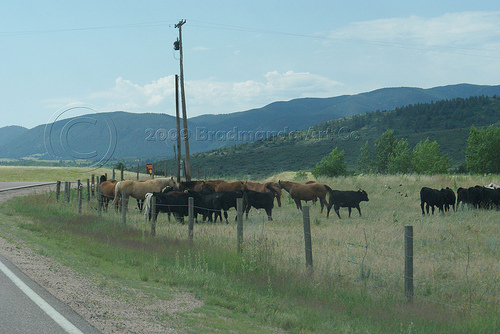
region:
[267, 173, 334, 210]
Horse grazing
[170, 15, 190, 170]
A power line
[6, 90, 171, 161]
mountains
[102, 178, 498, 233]
Livestock grazing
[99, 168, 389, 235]
Cows and horses grazing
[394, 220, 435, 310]
A pole for that is part of a fence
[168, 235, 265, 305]
grass and weeds on the roadside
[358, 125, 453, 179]
Green trees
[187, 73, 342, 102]
fluffy clouds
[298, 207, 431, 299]
Posts connected by wire to make a fence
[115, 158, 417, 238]
horses in a pasture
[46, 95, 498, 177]
mountains in the background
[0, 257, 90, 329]
white markings on the side of the road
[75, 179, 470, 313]
wooden fence with wires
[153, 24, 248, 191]
electrical wire post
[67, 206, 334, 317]
green plants growing by the side of the road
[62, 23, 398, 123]
clouds in the sky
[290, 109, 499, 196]
trees growing in the pasture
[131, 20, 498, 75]
electrical wires suspended in the air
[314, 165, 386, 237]
cow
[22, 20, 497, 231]
mountains are in the background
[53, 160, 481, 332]
a wooden fence with wire is around the animals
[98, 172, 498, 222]
horses and cows are grazing together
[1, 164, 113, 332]
a roadway is next to the field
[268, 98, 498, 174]
trees are in the hills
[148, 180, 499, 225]
the cows are black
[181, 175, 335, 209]
most horses are brown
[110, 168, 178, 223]
a light colored horse is next to the cows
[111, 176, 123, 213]
the horse has a long white tail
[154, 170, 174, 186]
the horse has a white mane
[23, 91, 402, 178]
name of copyright owner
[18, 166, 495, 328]
field of green grass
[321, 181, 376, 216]
black cow walking in grass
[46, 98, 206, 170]
dark mountains in horizon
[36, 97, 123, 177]
logo for copyright sign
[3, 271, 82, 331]
white line drawn in street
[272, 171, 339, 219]
brown horse in geen field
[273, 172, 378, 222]
brown horse and black cow next to each other green field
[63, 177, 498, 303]
metal fence bordering green field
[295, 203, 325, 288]
wooden fence support pole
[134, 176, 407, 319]
a fence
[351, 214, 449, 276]
a fence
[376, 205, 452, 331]
a fence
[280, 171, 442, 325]
a fence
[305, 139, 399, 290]
a fence